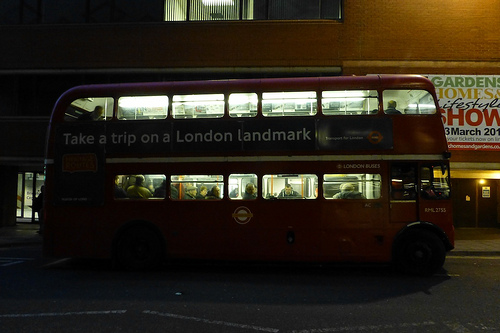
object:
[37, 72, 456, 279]
bus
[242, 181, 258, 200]
person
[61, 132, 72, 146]
letters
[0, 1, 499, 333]
scene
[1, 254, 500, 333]
road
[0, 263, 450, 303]
shadow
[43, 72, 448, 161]
top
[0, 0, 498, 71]
wall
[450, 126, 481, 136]
month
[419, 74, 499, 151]
sign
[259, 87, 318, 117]
window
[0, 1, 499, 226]
building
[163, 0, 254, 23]
window shades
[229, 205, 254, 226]
logo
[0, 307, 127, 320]
line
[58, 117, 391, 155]
sign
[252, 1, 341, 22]
window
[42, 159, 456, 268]
first level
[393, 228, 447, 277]
front wheel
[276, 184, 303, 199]
passenger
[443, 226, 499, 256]
sidewalk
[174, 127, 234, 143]
word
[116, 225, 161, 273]
tire